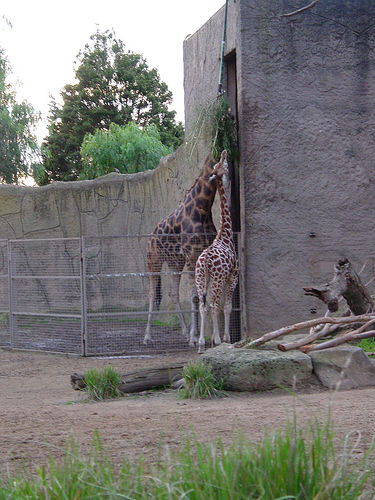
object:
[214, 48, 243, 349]
door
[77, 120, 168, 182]
leaves trees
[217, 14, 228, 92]
pole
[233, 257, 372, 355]
woods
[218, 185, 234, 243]
neck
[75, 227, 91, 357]
pole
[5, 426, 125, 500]
grass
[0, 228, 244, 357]
fence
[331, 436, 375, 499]
grass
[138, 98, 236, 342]
giraffe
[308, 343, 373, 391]
rock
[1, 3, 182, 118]
sky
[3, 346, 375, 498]
ground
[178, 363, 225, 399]
grass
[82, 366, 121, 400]
grass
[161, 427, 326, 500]
grass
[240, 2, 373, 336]
wall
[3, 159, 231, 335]
wall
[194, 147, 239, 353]
baby giraffe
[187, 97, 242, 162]
food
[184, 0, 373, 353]
building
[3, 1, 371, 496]
enclosure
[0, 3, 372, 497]
zoo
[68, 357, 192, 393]
log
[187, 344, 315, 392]
rock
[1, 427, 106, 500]
patch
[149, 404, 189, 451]
part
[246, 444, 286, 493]
part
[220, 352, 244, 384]
part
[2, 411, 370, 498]
foreground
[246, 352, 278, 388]
part